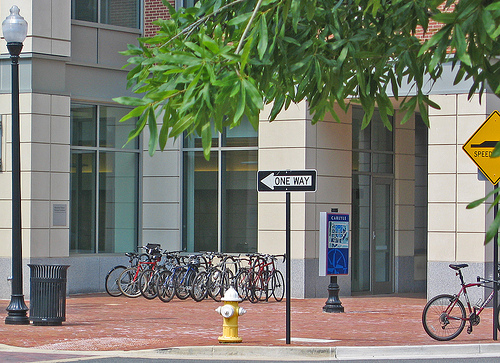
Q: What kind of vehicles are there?
A: Bicycles.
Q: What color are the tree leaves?
A: Green.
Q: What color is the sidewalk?
A: Red.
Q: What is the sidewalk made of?
A: Brick.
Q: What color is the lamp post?
A: Black.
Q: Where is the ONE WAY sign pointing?
A: To the left.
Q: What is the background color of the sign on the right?
A: Yellow.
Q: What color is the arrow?
A: White.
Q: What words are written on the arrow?
A: One Way.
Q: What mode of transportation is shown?
A: Bicycles.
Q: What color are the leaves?
A: Green.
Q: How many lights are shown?
A: 1.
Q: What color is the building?
A: White.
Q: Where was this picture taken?
A: This picture was taken on the street.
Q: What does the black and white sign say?
A: It says one way.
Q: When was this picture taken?
A: It was taken in the day time.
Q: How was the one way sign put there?
A: The person who did construction on this street put the sign there.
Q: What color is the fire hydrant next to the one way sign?
A: The fire hydrant is yellow and white.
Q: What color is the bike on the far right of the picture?
A: The bike is red.